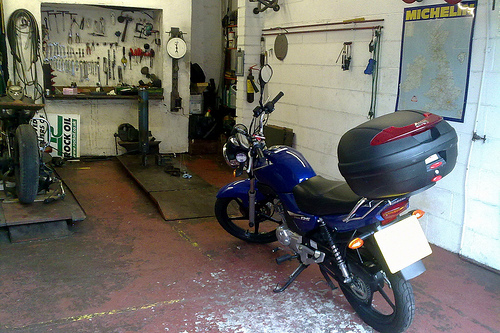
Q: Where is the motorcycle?
A: Garage.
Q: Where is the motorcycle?
A: Garage.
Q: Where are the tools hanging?
A: Wall.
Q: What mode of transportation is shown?
A: Motorcycyle.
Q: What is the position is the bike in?
A: Parked.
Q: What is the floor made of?
A: Concrete.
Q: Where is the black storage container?
A: Back of the bike.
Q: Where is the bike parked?
A: Garage.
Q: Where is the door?
A: Right side of the bike.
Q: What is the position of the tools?
A: Hanging on the wall.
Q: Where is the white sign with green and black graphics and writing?
A: Under the hanging tools.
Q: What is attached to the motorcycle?
A: Storage space attachment for a motorcycle.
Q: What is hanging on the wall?
A: Tools hanging on wall.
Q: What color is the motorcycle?
A: Blue.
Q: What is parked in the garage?
A: A motorcycle.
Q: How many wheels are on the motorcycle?
A: Two.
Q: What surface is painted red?
A: The floor.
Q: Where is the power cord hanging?
A: On the wall.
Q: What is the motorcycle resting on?
A: The kickstand.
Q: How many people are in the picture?
A: None.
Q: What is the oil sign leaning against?
A: The wall.